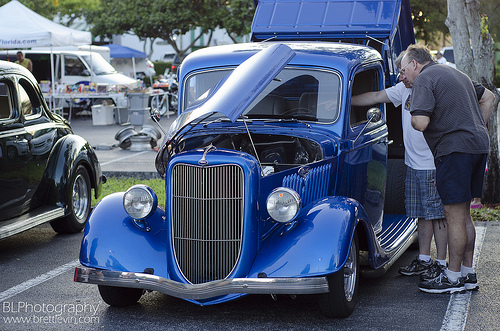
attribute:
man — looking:
[401, 42, 491, 295]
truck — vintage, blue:
[70, 1, 423, 318]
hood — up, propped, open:
[154, 43, 296, 178]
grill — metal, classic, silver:
[169, 161, 245, 284]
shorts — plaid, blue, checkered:
[403, 165, 446, 222]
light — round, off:
[121, 184, 154, 219]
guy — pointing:
[352, 51, 449, 281]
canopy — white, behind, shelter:
[0, 0, 97, 47]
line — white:
[440, 224, 485, 329]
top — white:
[383, 81, 437, 173]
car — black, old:
[0, 61, 107, 253]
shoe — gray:
[419, 274, 467, 295]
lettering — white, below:
[1, 301, 101, 324]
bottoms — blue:
[432, 151, 489, 207]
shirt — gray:
[408, 60, 489, 155]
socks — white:
[442, 266, 463, 282]